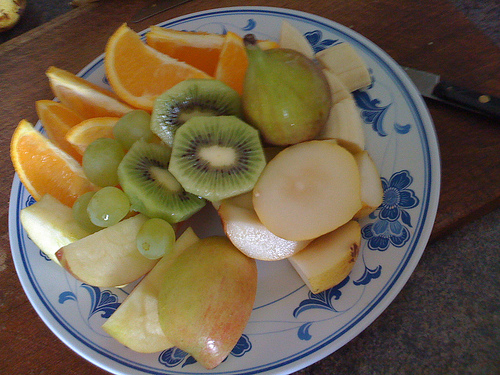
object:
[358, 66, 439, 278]
plate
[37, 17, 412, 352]
white plate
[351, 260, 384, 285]
plate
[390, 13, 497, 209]
board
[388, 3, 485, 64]
wooden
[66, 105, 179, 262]
grapes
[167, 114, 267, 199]
kiwi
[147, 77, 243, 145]
kiwi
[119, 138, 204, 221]
kiwi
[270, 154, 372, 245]
slice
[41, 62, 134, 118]
orange slice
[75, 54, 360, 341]
plate full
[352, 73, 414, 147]
design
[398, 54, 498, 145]
knife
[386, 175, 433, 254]
blue plate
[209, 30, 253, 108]
slice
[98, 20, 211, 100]
orange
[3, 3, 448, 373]
plate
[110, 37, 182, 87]
slice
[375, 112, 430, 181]
plate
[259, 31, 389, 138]
banana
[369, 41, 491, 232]
table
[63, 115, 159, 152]
orange slice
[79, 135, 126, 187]
grape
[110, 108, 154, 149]
grape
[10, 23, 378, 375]
fruit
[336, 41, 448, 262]
white plate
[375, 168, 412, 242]
blue design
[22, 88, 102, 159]
orange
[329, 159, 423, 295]
design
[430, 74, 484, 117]
handle